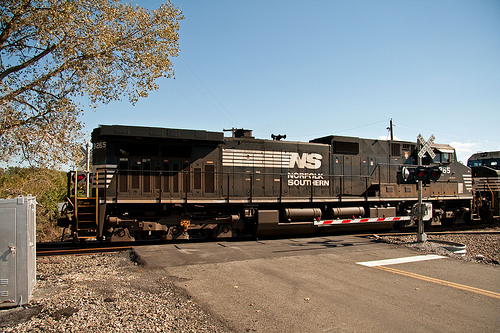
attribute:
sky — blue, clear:
[187, 2, 496, 122]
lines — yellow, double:
[374, 264, 493, 299]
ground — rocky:
[34, 233, 496, 331]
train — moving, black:
[58, 117, 499, 241]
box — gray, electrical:
[2, 189, 41, 315]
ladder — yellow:
[72, 166, 101, 248]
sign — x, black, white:
[411, 129, 439, 163]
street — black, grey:
[158, 238, 499, 332]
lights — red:
[66, 168, 90, 187]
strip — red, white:
[310, 214, 414, 228]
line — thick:
[353, 248, 448, 270]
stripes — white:
[220, 145, 293, 173]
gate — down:
[305, 209, 430, 247]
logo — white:
[217, 146, 336, 189]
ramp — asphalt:
[127, 226, 377, 251]